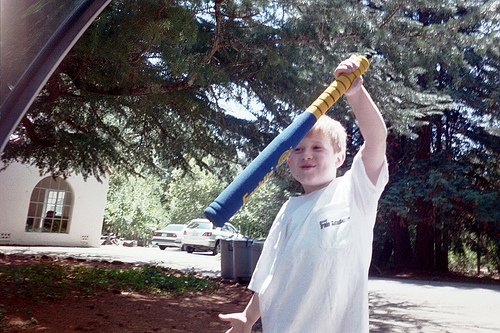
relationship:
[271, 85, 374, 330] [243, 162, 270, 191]
boy holding bat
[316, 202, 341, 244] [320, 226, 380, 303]
letters on shirt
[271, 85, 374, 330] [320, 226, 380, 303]
boy wearing shirt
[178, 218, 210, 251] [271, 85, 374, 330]
car behind boy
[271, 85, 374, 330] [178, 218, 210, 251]
boy near car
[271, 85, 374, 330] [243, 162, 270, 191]
boy with bat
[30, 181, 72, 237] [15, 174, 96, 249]
window on building